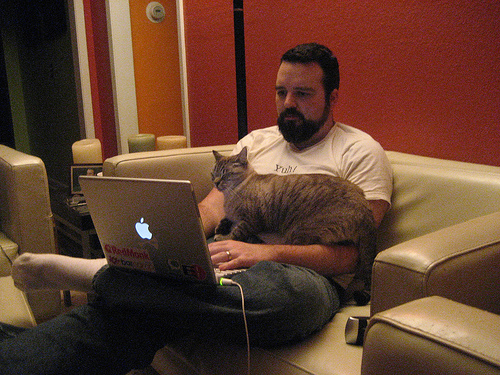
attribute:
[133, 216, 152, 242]
logo — glowing, apple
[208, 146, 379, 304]
cat — sleeping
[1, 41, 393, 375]
man — sitting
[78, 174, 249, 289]
laptop — apple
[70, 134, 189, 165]
candles — decorative, multicolored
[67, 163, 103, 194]
picture — small, framed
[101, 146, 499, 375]
chair — white, leather, beige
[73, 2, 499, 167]
wall — red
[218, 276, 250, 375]
cord — white